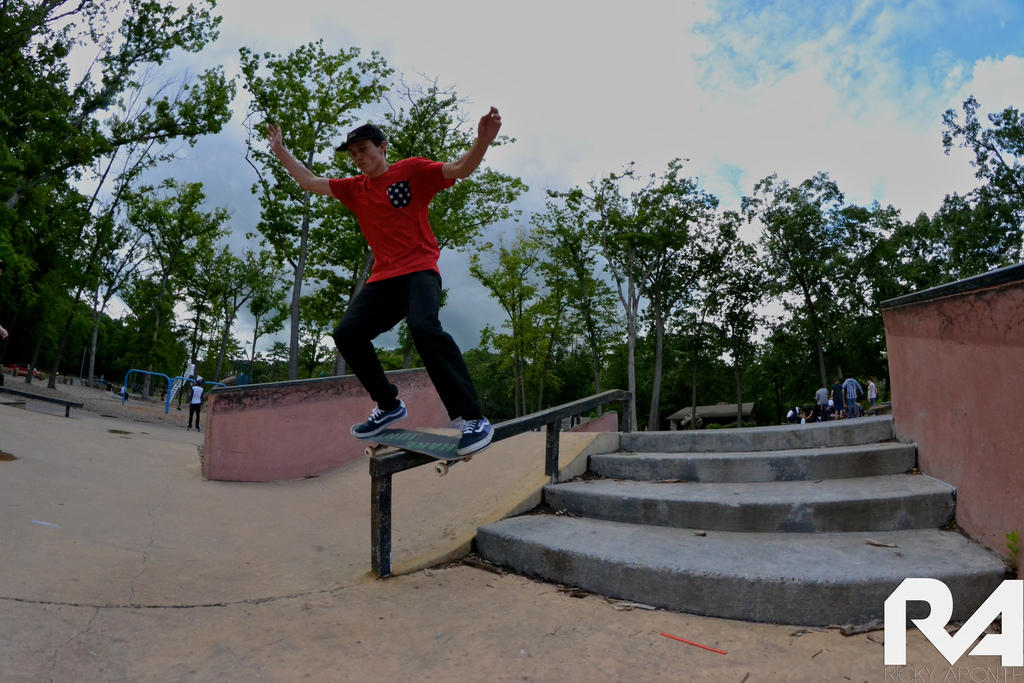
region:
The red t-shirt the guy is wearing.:
[317, 155, 450, 273]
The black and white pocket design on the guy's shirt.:
[387, 182, 411, 209]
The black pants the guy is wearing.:
[329, 261, 470, 411]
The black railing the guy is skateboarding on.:
[349, 384, 669, 581]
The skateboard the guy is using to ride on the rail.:
[367, 419, 470, 461]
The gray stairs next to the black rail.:
[457, 390, 1002, 610]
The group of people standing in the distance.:
[753, 362, 877, 427]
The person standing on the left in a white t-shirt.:
[179, 365, 206, 424]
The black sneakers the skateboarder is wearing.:
[352, 400, 496, 448]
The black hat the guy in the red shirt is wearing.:
[324, 118, 388, 144]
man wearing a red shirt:
[315, 154, 458, 276]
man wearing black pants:
[335, 252, 491, 423]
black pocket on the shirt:
[378, 171, 417, 201]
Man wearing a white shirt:
[183, 386, 204, 415]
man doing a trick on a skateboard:
[234, 97, 557, 472]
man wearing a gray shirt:
[812, 383, 838, 410]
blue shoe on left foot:
[438, 416, 512, 462]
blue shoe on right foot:
[328, 388, 424, 437]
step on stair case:
[584, 441, 921, 483]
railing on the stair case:
[359, 372, 636, 540]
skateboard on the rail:
[357, 416, 481, 475]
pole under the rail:
[359, 466, 418, 575]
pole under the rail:
[524, 407, 575, 491]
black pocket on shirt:
[379, 170, 418, 216]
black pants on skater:
[322, 262, 484, 422]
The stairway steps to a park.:
[483, 425, 1011, 644]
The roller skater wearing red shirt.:
[270, 109, 506, 471]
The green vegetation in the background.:
[0, 1, 1023, 428]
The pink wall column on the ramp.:
[196, 368, 438, 487]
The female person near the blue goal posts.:
[188, 378, 207, 424]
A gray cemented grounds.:
[0, 371, 1023, 679]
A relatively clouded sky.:
[28, 1, 1021, 360]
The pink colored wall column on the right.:
[882, 259, 1020, 569]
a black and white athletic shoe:
[454, 410, 493, 452]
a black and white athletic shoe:
[350, 398, 407, 433]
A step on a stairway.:
[476, 501, 1011, 618]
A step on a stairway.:
[539, 469, 958, 530]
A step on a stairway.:
[584, 435, 921, 481]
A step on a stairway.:
[619, 413, 895, 446]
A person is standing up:
[186, 377, 206, 429]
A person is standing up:
[866, 375, 879, 411]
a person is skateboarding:
[268, 106, 503, 476]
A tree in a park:
[591, 159, 741, 429]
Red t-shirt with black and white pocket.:
[310, 146, 454, 286]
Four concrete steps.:
[482, 410, 1007, 626]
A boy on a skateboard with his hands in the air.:
[261, 97, 512, 484]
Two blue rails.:
[118, 363, 230, 412]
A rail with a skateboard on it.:
[362, 382, 651, 582]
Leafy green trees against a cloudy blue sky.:
[0, 4, 1019, 428]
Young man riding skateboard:
[245, 81, 503, 478]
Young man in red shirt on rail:
[242, 113, 552, 491]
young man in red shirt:
[239, 79, 531, 498]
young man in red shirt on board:
[246, 85, 521, 491]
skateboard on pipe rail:
[348, 411, 494, 475]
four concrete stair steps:
[601, 407, 1017, 636]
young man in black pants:
[245, 101, 569, 476]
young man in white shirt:
[185, 373, 209, 449]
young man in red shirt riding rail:
[240, 88, 538, 484]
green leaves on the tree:
[717, 299, 746, 326]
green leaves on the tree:
[563, 255, 601, 316]